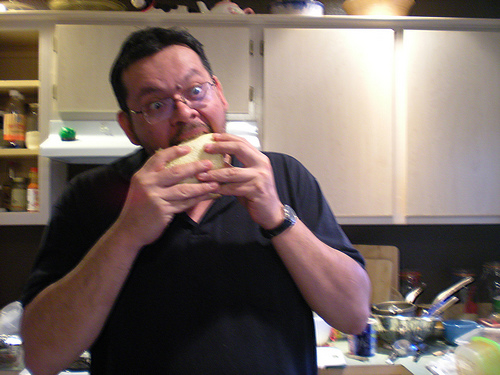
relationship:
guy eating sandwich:
[20, 25, 370, 375] [158, 126, 239, 204]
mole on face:
[171, 80, 184, 99] [122, 48, 227, 148]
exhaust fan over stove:
[40, 118, 263, 172] [72, 351, 88, 372]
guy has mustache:
[20, 25, 370, 375] [169, 119, 212, 144]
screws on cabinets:
[248, 38, 254, 55] [39, 7, 499, 225]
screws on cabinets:
[248, 85, 255, 101] [39, 7, 499, 225]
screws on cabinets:
[259, 39, 264, 54] [39, 7, 499, 225]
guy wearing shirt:
[20, 25, 370, 375] [18, 148, 365, 374]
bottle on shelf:
[3, 92, 25, 149] [0, 79, 46, 154]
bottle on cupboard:
[22, 167, 40, 213] [0, 29, 40, 213]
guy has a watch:
[20, 25, 370, 375] [256, 199, 299, 241]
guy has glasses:
[20, 25, 370, 375] [125, 76, 217, 123]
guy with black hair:
[24, 29, 374, 374] [109, 25, 216, 129]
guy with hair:
[24, 29, 374, 374] [108, 26, 215, 128]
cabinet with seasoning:
[0, 20, 51, 220] [5, 88, 22, 147]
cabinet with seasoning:
[0, 20, 51, 220] [24, 98, 41, 152]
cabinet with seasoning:
[0, 20, 51, 220] [8, 176, 25, 210]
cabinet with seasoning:
[0, 20, 51, 220] [26, 166, 38, 208]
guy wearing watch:
[20, 25, 370, 375] [253, 204, 343, 232]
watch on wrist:
[253, 204, 343, 232] [249, 191, 317, 238]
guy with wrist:
[20, 25, 370, 375] [249, 191, 317, 238]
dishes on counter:
[359, 275, 479, 362] [4, 284, 497, 372]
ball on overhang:
[41, 116, 116, 166] [37, 117, 260, 159]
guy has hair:
[20, 25, 370, 375] [101, 26, 221, 76]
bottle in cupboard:
[0, 85, 30, 147] [2, 77, 44, 224]